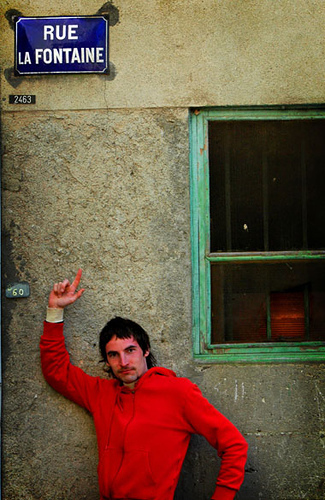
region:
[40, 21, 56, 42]
White letter on a blue sign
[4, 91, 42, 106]
Black and white sign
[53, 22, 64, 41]
White letter on a blue sign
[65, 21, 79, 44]
White letter on a blue sign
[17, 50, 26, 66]
White letter on a blue sign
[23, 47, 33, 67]
White letter on a blue sign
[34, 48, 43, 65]
White letter on a blue sign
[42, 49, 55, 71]
White letter on a blue sign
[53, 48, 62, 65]
White letter on a blue sign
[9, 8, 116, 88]
White and blue sign on a wall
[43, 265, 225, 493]
man is standing up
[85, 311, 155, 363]
man has brown hair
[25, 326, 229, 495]
the jacket is red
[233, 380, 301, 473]
the wall is made of rock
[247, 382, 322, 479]
the wall is gray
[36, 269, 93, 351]
man has hand in the air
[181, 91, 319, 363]
window in the building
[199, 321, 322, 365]
window sill is green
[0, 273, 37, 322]
number on the building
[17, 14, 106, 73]
Blue sign on wall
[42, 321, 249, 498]
Red hoodie on man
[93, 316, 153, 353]
Black hair on man's head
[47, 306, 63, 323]
White shirt cuff on man's wrist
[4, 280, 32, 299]
Small block with number on it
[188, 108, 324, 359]
Green frame around window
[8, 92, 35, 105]
Black block with number on it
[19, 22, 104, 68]
White letters on blue sign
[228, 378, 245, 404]
White scratches on wall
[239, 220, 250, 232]
White mark on glass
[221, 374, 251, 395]
white marks in stone wall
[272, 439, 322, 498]
scratches in stone wall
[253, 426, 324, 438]
crack in stone wall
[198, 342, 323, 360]
base of green window frame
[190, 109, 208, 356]
side of wooden window frame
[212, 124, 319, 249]
glass for looking through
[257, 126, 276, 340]
green bars on inside of building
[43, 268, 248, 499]
man standing against wall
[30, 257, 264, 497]
man is pointing to sign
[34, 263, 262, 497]
man in a red jacket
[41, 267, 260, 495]
man has brown hair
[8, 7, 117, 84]
blue sign on wall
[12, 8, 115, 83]
blue sign with white letters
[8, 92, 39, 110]
small black sign with numbers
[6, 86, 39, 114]
small black sign on wall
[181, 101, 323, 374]
window with green sill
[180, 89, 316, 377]
this window is closed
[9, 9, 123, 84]
blue and white sign on building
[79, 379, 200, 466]
The jacket is red.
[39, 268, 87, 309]
A man holding up finger.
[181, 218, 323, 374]
Window pane is green.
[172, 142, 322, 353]
Window on the wall.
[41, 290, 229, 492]
Man leaning against the wall.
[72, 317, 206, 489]
Man wearing red jacket.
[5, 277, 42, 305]
A number 60 on the wall.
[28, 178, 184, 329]
The wall is dirty.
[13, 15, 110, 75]
Blue rectangle sign that says RUE LA FONTAINE on it.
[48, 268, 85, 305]
Man's hand with finger pointed.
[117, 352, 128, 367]
Nose on a mans face.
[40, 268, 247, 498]
Man in orange sweatshirt with finger pointed.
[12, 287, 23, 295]
The number 60.